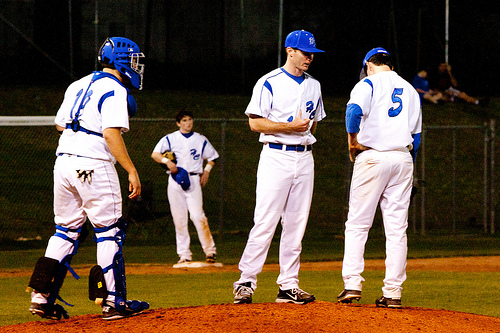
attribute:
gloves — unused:
[74, 167, 96, 184]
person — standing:
[151, 112, 220, 259]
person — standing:
[225, 25, 330, 311]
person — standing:
[338, 37, 431, 309]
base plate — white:
[167, 249, 227, 276]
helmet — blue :
[93, 32, 138, 84]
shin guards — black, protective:
[28, 250, 130, 320]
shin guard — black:
[112, 252, 129, 306]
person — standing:
[21, 30, 149, 330]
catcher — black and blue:
[24, 26, 154, 316]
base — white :
[171, 260, 224, 270]